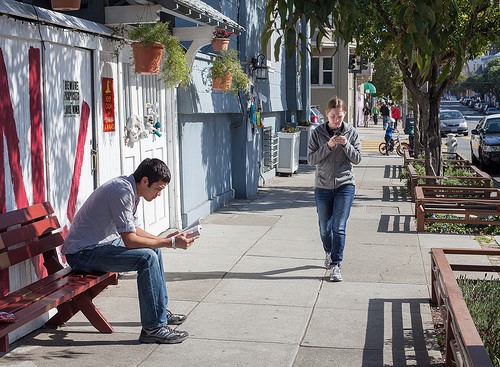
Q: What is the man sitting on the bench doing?
A: Reading a book.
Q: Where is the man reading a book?
A: On a bench.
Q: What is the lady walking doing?
A: Looking at phone.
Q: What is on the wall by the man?
A: White double doors with windows.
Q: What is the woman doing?
A: Walking and texting.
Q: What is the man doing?
A: Reading.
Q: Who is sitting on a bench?
A: A young man.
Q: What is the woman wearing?
A: Gray hoodie.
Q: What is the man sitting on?
A: A red bench.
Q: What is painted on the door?
A: Red stripes.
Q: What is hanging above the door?
A: Flower pots.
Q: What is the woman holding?
A: A phone.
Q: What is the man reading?
A: A book.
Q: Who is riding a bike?
A: A child.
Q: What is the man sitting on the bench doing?
A: The man is reading a book.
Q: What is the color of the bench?
A: The color is red.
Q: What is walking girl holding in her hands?
A: She is holding a phone.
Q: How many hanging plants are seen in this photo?
A: Three hanging plants.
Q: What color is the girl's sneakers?
A: The color is white.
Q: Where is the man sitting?
A: The man is sitting on a bench.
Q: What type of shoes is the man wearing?
A: The man is wearing sneakers.